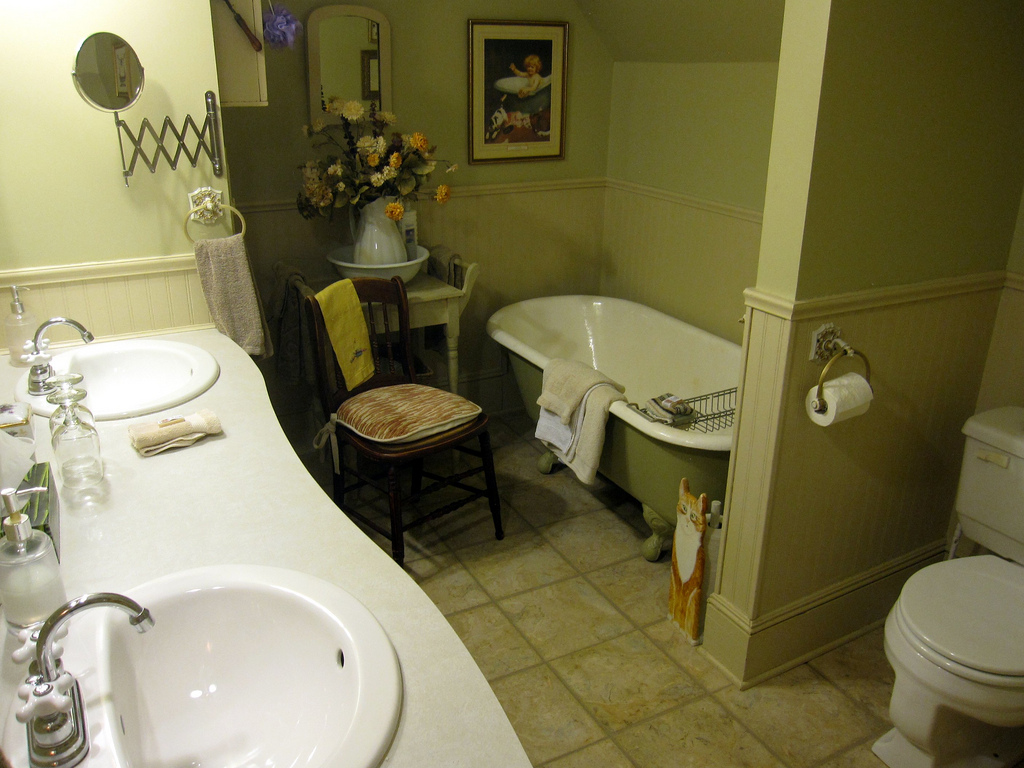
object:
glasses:
[44, 374, 103, 491]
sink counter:
[0, 322, 533, 764]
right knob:
[11, 623, 68, 664]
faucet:
[12, 592, 158, 765]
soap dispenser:
[1, 487, 68, 629]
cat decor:
[667, 477, 707, 646]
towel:
[128, 408, 222, 456]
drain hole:
[336, 648, 344, 668]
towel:
[314, 278, 375, 391]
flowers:
[297, 97, 461, 221]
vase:
[353, 196, 408, 266]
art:
[467, 18, 570, 166]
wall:
[221, 1, 612, 455]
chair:
[305, 275, 507, 567]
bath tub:
[486, 294, 744, 564]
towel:
[535, 356, 628, 484]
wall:
[0, 0, 234, 354]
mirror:
[71, 32, 223, 187]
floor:
[297, 414, 1023, 767]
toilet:
[870, 404, 1024, 767]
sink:
[9, 564, 402, 767]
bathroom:
[0, 0, 1024, 765]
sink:
[14, 340, 220, 422]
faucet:
[21, 317, 94, 396]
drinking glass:
[46, 389, 104, 489]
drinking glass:
[44, 373, 94, 436]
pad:
[312, 383, 483, 475]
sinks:
[2, 337, 407, 766]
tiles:
[299, 410, 1022, 767]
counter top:
[0, 328, 534, 767]